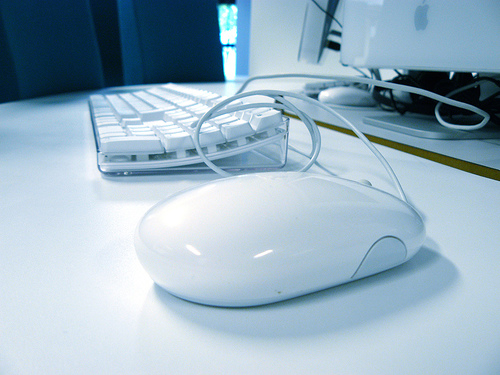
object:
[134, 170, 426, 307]
mouse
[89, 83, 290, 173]
keyboard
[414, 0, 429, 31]
icon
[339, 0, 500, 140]
computer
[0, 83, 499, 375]
table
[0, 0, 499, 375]
room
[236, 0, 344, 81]
wall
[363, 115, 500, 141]
stand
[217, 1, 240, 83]
window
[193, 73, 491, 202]
wire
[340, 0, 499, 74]
monitor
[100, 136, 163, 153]
key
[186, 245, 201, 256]
reflection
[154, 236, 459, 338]
shadow